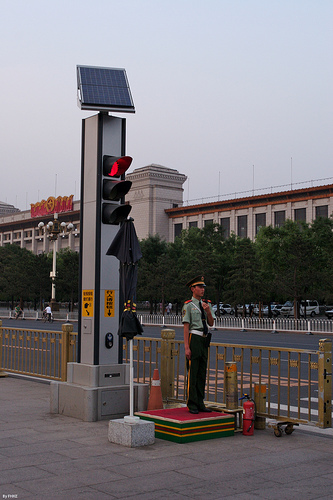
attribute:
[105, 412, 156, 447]
cement block — heavy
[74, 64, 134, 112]
solar panel — black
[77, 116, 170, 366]
light — solar powered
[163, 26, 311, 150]
clouds — white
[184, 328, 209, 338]
belt — white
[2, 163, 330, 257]
building — long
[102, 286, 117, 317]
sign — black, yellow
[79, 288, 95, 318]
sign — black, yellow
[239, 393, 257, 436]
fire extinguisher — red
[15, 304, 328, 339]
fence — long, white, metal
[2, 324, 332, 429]
railing — yellow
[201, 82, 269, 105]
clouds — white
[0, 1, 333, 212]
sky — blue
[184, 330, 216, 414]
pants — green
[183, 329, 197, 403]
stripe — yellow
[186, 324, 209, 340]
belt — utility belt, white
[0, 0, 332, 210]
clouds — white